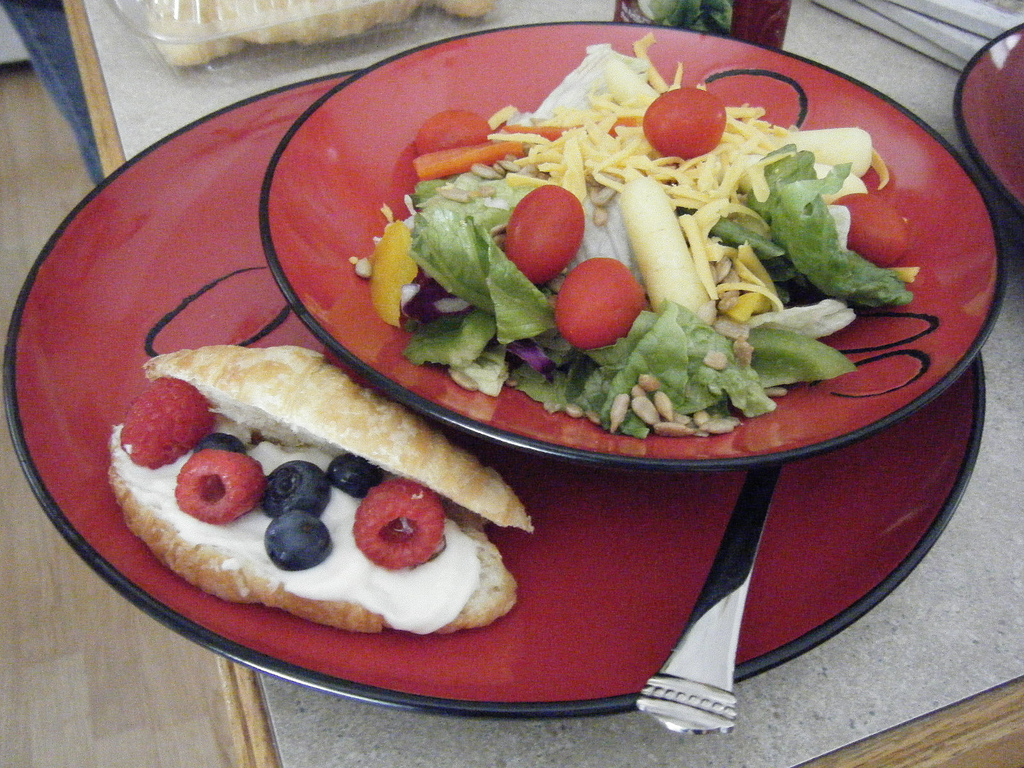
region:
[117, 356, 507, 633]
a croissant on a plate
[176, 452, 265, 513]
a rasperry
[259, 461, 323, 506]
a blueberry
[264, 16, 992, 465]
a red plate of food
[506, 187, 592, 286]
a tomato on the plate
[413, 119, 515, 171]
carrots on the plate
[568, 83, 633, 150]
cheese on the salad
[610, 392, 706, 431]
sunflower seen kernels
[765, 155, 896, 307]
lettuce on the plate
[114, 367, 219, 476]
Red raspberries are full of nutrients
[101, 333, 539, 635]
bread filled with berries and cream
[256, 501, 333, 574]
Blueberries are healthy and full of nutrients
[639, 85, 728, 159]
Red cherry tomatoes are perfect in salad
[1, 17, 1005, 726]
Red dish set with black trim and designs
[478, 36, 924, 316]
shredded cheese on salads are better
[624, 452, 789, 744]
Silverware with decorative designs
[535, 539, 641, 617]
the plate is red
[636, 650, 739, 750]
a handle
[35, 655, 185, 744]
the wooden floor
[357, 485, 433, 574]
a rasberry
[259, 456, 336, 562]
a blue berry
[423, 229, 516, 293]
lettuce on the plate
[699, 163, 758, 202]
cheese on the plate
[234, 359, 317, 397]
a crossant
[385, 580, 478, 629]
cream cheese is white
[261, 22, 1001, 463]
a red and black bowl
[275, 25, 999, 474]
a bowl containing a salad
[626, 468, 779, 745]
the handle of silverware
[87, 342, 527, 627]
a croissant with berries in it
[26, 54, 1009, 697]
a plate on a counter top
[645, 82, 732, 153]
a small red grape tomato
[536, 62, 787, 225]
yellow shredded cheese on a salad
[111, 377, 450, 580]
blueberries and raspberries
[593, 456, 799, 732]
the utensil is metal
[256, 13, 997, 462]
the smaller red plate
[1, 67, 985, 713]
the larger red plate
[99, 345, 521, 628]
the croissant has cream in it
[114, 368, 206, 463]
the raspberry farthest away from the utensil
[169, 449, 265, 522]
the raspberry in the middle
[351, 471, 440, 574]
the raspberry closest to the utensil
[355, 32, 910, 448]
the salad on the smaller red plate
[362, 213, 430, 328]
the yellow pepper on the red plate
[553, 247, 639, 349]
A red tomato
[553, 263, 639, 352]
Tomato is red.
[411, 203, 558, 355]
A piece of lettuce that is green.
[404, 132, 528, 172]
A piece of carrot that is orange.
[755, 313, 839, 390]
A piece of pepper that is green.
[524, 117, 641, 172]
Shedded cheese that is yellow.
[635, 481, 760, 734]
A fork on the side of the bowl.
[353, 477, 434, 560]
Red rasberries on the slice of bread.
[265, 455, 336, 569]
Blue blueberries on the slice of bread.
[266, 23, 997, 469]
A red and black bowl.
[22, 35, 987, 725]
A red and black plate.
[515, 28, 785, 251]
shredded cheese on top of salad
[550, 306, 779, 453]
sunflower seeds on top of sallad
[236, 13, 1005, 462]
red salad bowl with black trim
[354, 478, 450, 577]
a cut red raspberry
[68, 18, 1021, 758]
the grey countertop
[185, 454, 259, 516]
a red raspberry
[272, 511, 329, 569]
a blue blueberry